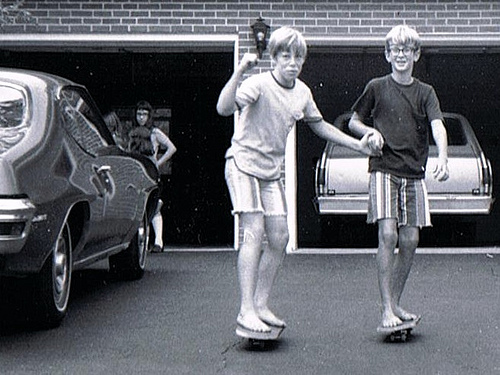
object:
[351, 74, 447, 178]
dark t-shirt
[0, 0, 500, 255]
house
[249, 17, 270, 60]
fixture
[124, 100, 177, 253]
girl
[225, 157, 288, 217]
short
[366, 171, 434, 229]
short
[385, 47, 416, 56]
eyeglasses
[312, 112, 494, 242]
car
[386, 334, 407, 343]
wheels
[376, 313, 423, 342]
skateboard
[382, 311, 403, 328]
feet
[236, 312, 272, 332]
feet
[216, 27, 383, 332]
boy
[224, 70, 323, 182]
white shirt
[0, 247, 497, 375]
sidewalk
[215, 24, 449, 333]
kids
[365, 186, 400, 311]
leg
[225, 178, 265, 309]
leg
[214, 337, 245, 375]
crack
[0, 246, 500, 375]
ground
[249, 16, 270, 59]
monitor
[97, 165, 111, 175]
door handle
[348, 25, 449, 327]
boy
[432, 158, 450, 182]
hand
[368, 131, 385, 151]
hand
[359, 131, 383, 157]
hand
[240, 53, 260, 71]
hand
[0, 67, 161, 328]
car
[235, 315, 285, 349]
skateboard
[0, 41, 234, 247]
garage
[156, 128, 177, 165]
arm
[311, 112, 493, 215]
back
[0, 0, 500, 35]
bricks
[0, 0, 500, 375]
background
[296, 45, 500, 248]
garage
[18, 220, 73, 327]
tires